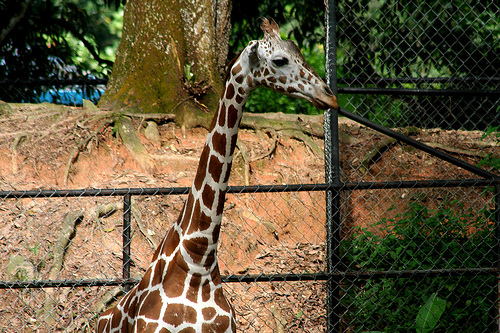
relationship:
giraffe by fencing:
[90, 19, 338, 328] [1, 183, 498, 330]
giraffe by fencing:
[90, 19, 338, 328] [324, 0, 497, 330]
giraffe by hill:
[90, 19, 338, 328] [0, 104, 497, 329]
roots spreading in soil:
[68, 96, 155, 164] [7, 102, 201, 187]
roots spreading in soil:
[247, 112, 326, 153] [240, 110, 323, 181]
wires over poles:
[1, 0, 484, 330] [2, 178, 495, 325]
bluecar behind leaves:
[22, 47, 104, 109] [0, 5, 117, 106]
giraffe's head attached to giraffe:
[233, 16, 340, 113] [90, 19, 338, 328]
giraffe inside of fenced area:
[90, 19, 338, 328] [0, 0, 485, 330]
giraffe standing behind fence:
[84, 16, 338, 332] [276, 187, 388, 280]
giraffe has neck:
[90, 19, 338, 328] [158, 63, 253, 265]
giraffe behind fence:
[90, 19, 338, 328] [48, 131, 403, 328]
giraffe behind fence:
[90, 19, 338, 328] [331, 0, 498, 332]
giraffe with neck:
[90, 19, 338, 328] [178, 68, 255, 252]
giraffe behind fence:
[90, 19, 338, 328] [0, 2, 485, 330]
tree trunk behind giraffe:
[98, 0, 231, 110] [214, 20, 333, 121]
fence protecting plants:
[331, 0, 498, 332] [327, 194, 499, 331]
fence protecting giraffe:
[331, 0, 498, 332] [90, 19, 338, 328]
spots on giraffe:
[163, 275, 230, 330] [90, 19, 338, 328]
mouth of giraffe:
[291, 80, 340, 120] [90, 19, 338, 328]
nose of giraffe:
[314, 80, 335, 107] [90, 19, 338, 328]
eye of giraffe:
[268, 56, 290, 68] [90, 19, 338, 328]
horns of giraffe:
[256, 16, 291, 37] [61, 15, 357, 325]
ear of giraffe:
[243, 38, 260, 53] [90, 19, 338, 328]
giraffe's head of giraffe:
[233, 16, 340, 113] [90, 19, 338, 328]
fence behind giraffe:
[331, 0, 498, 332] [90, 19, 338, 328]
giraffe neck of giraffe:
[153, 72, 266, 263] [102, 2, 341, 325]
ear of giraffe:
[247, 38, 260, 66] [90, 19, 338, 328]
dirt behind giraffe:
[31, 137, 207, 187] [90, 19, 338, 328]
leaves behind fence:
[322, 41, 499, 136] [339, 33, 469, 280]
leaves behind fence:
[346, 194, 491, 324] [339, 33, 469, 280]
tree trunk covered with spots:
[98, 0, 231, 110] [134, 20, 177, 53]